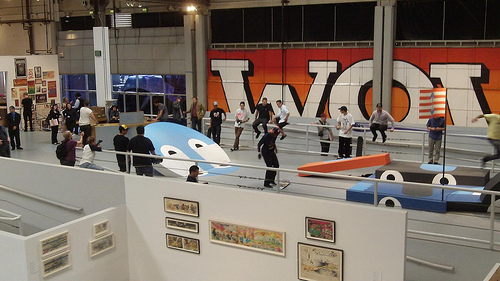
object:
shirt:
[81, 140, 99, 164]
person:
[230, 101, 250, 151]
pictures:
[13, 57, 31, 79]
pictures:
[35, 78, 46, 86]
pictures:
[13, 78, 27, 87]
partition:
[21, 196, 135, 275]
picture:
[33, 66, 43, 79]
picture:
[33, 91, 48, 103]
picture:
[10, 87, 19, 99]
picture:
[51, 82, 59, 101]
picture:
[93, 219, 111, 235]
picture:
[89, 231, 115, 258]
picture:
[40, 250, 72, 278]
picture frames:
[38, 217, 114, 277]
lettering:
[208, 55, 494, 127]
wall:
[208, 42, 499, 128]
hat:
[118, 124, 130, 130]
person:
[113, 125, 133, 174]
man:
[113, 125, 132, 175]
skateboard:
[263, 180, 291, 190]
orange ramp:
[297, 152, 391, 177]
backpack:
[55, 140, 68, 160]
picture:
[13, 57, 28, 81]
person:
[337, 105, 355, 159]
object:
[143, 121, 240, 177]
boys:
[367, 102, 395, 144]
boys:
[272, 100, 290, 140]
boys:
[252, 97, 276, 139]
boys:
[310, 113, 334, 156]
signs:
[9, 57, 57, 107]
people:
[79, 135, 104, 171]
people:
[55, 129, 84, 167]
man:
[257, 127, 282, 189]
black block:
[375, 160, 491, 186]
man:
[471, 114, 500, 171]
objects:
[344, 162, 499, 215]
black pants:
[260, 151, 279, 188]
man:
[5, 106, 24, 151]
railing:
[70, 143, 499, 255]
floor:
[3, 121, 498, 277]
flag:
[418, 88, 447, 120]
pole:
[440, 86, 450, 179]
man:
[78, 103, 99, 148]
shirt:
[48, 96, 86, 133]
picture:
[163, 196, 200, 217]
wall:
[2, 151, 412, 277]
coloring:
[203, 43, 497, 127]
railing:
[192, 116, 457, 167]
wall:
[38, 56, 59, 71]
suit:
[126, 134, 156, 176]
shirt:
[335, 115, 356, 140]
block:
[297, 153, 391, 177]